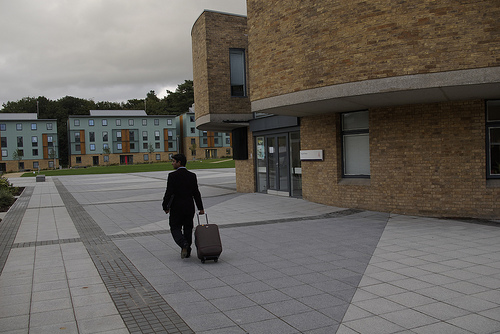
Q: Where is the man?
A: On the walkway.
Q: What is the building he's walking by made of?
A: Bricks.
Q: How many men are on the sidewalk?
A: One.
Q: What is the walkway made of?
A: Square cobblestones.